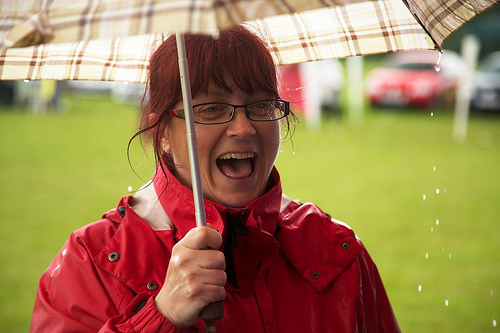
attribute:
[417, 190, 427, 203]
rain — falling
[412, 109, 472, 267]
rain drop — falling, clear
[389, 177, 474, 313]
rain drop — clear, falling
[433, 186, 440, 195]
drop — clear, falling, rain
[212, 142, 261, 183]
mouth — open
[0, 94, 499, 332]
grass — green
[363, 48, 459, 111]
car — red, parked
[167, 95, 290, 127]
eyeglasses — narrow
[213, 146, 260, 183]
mouth — open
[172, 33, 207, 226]
handle — silver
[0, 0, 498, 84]
umbrella — brown, plaid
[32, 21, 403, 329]
jacket — red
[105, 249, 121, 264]
snap — silver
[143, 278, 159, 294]
snap — silver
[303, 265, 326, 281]
snap — silver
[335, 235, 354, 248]
snap — silver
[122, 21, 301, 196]
hair — red, stringy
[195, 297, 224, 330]
handle — black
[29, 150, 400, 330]
jacket — red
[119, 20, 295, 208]
hair — red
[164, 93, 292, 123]
glass rims — thin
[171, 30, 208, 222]
rod — silver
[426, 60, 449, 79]
drop — water, rain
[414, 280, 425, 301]
drop — rain , water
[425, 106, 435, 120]
rain drop — clear, falling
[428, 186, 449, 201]
rain drop — clear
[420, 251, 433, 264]
rain drop — clear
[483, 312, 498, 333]
rain drop — clear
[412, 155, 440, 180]
rain drop — clear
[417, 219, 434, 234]
rain drop — clear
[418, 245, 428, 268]
rain drop — clear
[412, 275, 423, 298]
rain drop — clear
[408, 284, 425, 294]
rain drop — clear